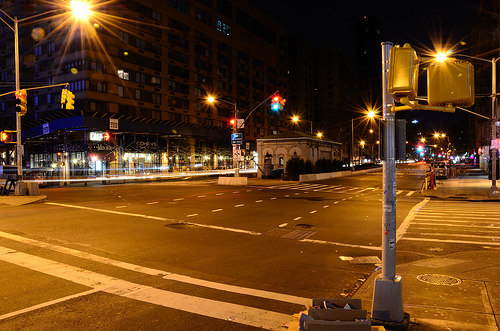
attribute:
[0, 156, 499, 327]
street — empty, in city, very crowded, extremely quiet, completely empty, intersection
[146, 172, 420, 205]
crosswalk — to walk, where you cross, for pedestrians, white lined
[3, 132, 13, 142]
sign — for do not walk, red, so you won't go, for no walking, cross walk light, yellow, cross walk sign, pedestrian signal, for pedestrians, crossing signal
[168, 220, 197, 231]
sewer hole — covered up, closed, covered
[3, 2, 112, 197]
street light — on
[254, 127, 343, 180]
building — little, cool, tall, stone, in the median, sitting on median, small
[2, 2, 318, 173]
building — on the left, big, tall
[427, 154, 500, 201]
sidewalk — paved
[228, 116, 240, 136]
stop light — blinking red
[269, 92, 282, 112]
stop light — blinking green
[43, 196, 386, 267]
line — white, solid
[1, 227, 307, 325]
line — white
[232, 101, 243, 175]
pole — for lamp, metal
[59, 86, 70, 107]
pedestrian signal — the back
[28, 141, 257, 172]
shop — closed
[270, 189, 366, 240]
dotted line — white